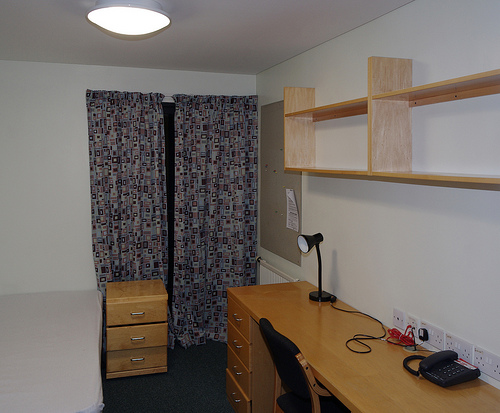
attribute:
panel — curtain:
[85, 88, 173, 348]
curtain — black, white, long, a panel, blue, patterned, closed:
[172, 93, 259, 348]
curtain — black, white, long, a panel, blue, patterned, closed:
[85, 89, 174, 349]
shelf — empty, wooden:
[285, 94, 367, 117]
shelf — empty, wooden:
[372, 68, 500, 101]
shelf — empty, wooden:
[284, 166, 368, 178]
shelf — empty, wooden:
[369, 170, 499, 186]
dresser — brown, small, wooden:
[104, 279, 170, 380]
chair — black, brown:
[257, 317, 350, 413]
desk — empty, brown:
[225, 280, 500, 413]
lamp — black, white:
[296, 232, 332, 302]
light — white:
[86, 6, 172, 36]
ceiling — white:
[2, 1, 415, 74]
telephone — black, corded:
[404, 350, 482, 387]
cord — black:
[329, 299, 430, 354]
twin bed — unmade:
[1, 289, 103, 413]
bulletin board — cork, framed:
[258, 99, 303, 268]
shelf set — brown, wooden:
[282, 56, 499, 190]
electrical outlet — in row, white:
[473, 346, 500, 379]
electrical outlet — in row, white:
[443, 332, 471, 365]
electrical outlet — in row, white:
[418, 318, 444, 353]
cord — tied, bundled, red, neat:
[387, 324, 417, 346]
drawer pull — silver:
[131, 311, 143, 316]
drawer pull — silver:
[131, 336, 145, 342]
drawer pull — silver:
[130, 357, 143, 362]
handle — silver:
[232, 311, 244, 322]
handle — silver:
[231, 337, 242, 350]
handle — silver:
[231, 363, 245, 377]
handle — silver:
[229, 390, 243, 405]